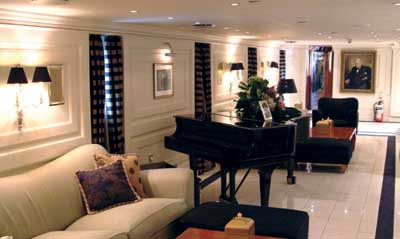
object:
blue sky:
[163, 109, 297, 206]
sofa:
[0, 142, 196, 237]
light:
[5, 61, 31, 136]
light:
[30, 65, 52, 120]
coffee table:
[175, 198, 310, 238]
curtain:
[90, 33, 125, 156]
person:
[274, 94, 288, 118]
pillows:
[75, 151, 149, 215]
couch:
[0, 142, 196, 238]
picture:
[151, 61, 175, 97]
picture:
[341, 45, 375, 94]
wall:
[1, 23, 399, 176]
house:
[0, 0, 399, 238]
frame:
[152, 62, 176, 99]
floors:
[191, 134, 400, 238]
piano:
[162, 113, 300, 207]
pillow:
[73, 157, 144, 212]